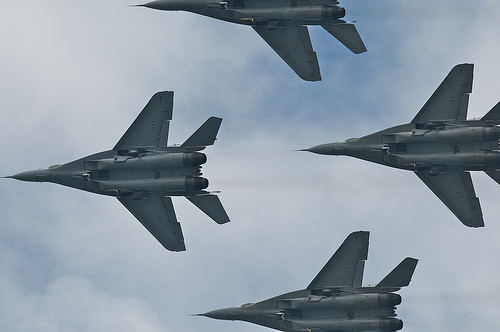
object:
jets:
[13, 5, 492, 324]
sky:
[2, 2, 499, 331]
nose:
[1, 169, 47, 191]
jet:
[3, 85, 240, 268]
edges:
[94, 116, 138, 155]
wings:
[79, 87, 201, 257]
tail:
[176, 107, 239, 231]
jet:
[280, 50, 499, 245]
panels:
[110, 148, 144, 165]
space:
[171, 102, 199, 142]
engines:
[179, 149, 213, 192]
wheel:
[427, 167, 442, 176]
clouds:
[8, 6, 249, 96]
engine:
[143, 149, 212, 170]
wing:
[110, 192, 191, 256]